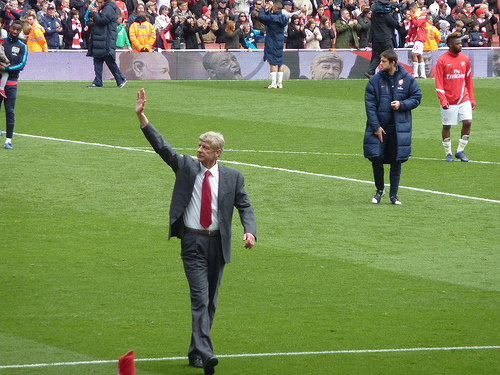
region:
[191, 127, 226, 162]
the head of a man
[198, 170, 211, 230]
a red tie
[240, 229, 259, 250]
the hand of a man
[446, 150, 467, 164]
a pair of blue shoes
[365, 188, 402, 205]
a pair of black and white shoes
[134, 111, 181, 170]
the arm of a man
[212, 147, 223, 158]
the ear of a man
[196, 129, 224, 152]
the gray hair of a man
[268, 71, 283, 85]
tall white socks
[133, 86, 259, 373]
a man in a suit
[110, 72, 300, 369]
the man is wearing a suit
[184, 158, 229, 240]
the man has a red tie on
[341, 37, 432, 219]
this man is wearing a puffy coat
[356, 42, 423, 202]
the puffy coat is dark blue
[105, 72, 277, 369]
the man is waving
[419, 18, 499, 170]
the man is wearing a red shirt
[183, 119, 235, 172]
the man has light colored hair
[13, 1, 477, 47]
there are many spectators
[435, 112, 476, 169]
the man is wearing shin guards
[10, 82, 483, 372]
this appears to be a soccer field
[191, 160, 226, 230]
Man wearing red tie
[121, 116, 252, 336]
Man wearing gray suit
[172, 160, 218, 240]
Man wearing white shirt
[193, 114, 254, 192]
Man has gray hair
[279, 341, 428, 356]
White lines on field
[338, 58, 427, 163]
Person wearing large blue jacket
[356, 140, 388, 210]
Person wearing dark pants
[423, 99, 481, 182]
Player wearing white shorts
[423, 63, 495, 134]
Player wearing red and white shirt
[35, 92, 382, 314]
Field is green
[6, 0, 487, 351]
multiple people walking on a field.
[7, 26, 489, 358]
people out on a ball field.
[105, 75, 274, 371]
a man walking in a suit.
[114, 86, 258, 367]
man dressed in gray suit.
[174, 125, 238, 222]
man wearing a white shirt and red tie.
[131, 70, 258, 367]
a man in suit waving his arm.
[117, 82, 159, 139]
right hand of a person.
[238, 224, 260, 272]
left hand of a person.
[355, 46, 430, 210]
man wearing dark clothing.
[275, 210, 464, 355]
green patch of grass on field.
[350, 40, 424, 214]
Man wearing a very long puffy coat.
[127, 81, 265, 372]
Man in a suit waving to the crowd.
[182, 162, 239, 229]
White shirt and red tie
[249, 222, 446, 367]
Green grassy playing field.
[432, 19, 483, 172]
Man in a red and white athletic uniform.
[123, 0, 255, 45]
Crowd of fans sitting in stands.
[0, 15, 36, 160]
Man holding a child.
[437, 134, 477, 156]
Shin guards on players shins.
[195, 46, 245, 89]
Picture of a man with his mouth wide open.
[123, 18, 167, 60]
Bright yellow jacket.